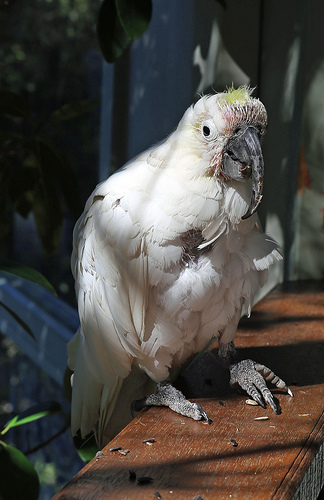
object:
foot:
[215, 348, 298, 415]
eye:
[200, 122, 215, 143]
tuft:
[218, 81, 257, 104]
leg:
[213, 339, 295, 409]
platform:
[49, 279, 323, 499]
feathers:
[217, 82, 250, 108]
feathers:
[55, 29, 303, 433]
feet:
[142, 367, 214, 431]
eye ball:
[201, 125, 213, 139]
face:
[186, 85, 284, 219]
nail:
[265, 392, 285, 414]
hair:
[221, 80, 246, 104]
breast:
[155, 205, 238, 306]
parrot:
[55, 81, 299, 454]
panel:
[62, 389, 319, 499]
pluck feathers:
[171, 218, 214, 267]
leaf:
[113, 0, 153, 39]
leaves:
[1, 0, 155, 256]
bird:
[63, 79, 294, 451]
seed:
[254, 414, 267, 420]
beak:
[225, 127, 258, 189]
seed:
[216, 399, 228, 406]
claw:
[225, 361, 294, 417]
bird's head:
[176, 74, 272, 211]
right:
[154, 368, 213, 427]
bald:
[160, 259, 210, 310]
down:
[9, 378, 40, 474]